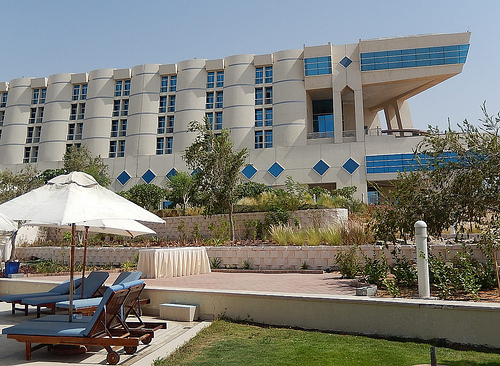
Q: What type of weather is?
A: It is clear.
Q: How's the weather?
A: It is clear.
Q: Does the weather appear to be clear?
A: Yes, it is clear.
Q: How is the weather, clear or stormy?
A: It is clear.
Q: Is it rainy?
A: No, it is clear.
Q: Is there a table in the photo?
A: Yes, there is a table.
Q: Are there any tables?
A: Yes, there is a table.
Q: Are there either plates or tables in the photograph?
A: Yes, there is a table.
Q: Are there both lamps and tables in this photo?
A: No, there is a table but no lamps.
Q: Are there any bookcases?
A: No, there are no bookcases.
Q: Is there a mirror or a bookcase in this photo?
A: No, there are no bookcases or mirrors.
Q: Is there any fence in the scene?
A: No, there are no fences.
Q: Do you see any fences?
A: No, there are no fences.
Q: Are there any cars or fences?
A: No, there are no fences or cars.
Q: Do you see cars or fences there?
A: No, there are no fences or cars.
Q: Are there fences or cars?
A: No, there are no fences or cars.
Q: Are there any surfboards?
A: No, there are no surfboards.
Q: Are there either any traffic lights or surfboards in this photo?
A: No, there are no surfboards or traffic lights.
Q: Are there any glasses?
A: No, there are no glasses.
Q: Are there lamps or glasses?
A: No, there are no glasses or lamps.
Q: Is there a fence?
A: No, there are no fences.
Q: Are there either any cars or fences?
A: No, there are no fences or cars.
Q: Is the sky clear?
A: Yes, the sky is clear.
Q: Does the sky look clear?
A: Yes, the sky is clear.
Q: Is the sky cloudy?
A: No, the sky is clear.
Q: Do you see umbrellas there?
A: Yes, there is an umbrella.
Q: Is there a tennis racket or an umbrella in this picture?
A: Yes, there is an umbrella.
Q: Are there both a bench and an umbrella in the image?
A: No, there is an umbrella but no benches.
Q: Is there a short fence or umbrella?
A: Yes, there is a short umbrella.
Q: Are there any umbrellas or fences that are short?
A: Yes, the umbrella is short.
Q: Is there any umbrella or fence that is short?
A: Yes, the umbrella is short.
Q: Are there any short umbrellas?
A: Yes, there is a short umbrella.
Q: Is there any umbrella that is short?
A: Yes, there is an umbrella that is short.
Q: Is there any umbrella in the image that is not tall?
A: Yes, there is a short umbrella.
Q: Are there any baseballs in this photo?
A: No, there are no baseballs.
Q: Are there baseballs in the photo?
A: No, there are no baseballs.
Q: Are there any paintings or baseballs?
A: No, there are no baseballs or paintings.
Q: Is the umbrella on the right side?
A: No, the umbrella is on the left of the image.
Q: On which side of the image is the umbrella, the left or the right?
A: The umbrella is on the left of the image.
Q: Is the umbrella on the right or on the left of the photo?
A: The umbrella is on the left of the image.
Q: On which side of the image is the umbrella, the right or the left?
A: The umbrella is on the left of the image.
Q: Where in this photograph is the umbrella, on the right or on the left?
A: The umbrella is on the left of the image.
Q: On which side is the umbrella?
A: The umbrella is on the left of the image.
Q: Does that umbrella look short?
A: Yes, the umbrella is short.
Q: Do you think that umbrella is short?
A: Yes, the umbrella is short.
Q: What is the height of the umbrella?
A: The umbrella is short.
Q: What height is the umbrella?
A: The umbrella is short.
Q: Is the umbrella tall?
A: No, the umbrella is short.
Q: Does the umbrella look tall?
A: No, the umbrella is short.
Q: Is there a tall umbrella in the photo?
A: No, there is an umbrella but it is short.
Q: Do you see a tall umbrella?
A: No, there is an umbrella but it is short.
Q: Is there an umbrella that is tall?
A: No, there is an umbrella but it is short.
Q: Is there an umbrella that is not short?
A: No, there is an umbrella but it is short.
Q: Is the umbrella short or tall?
A: The umbrella is short.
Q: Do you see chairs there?
A: Yes, there is a chair.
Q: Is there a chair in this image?
A: Yes, there is a chair.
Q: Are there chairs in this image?
A: Yes, there is a chair.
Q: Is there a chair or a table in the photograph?
A: Yes, there is a chair.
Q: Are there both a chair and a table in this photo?
A: Yes, there are both a chair and a table.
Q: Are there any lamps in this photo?
A: No, there are no lamps.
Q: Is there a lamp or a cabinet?
A: No, there are no lamps or cabinets.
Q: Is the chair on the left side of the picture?
A: Yes, the chair is on the left of the image.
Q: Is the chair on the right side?
A: No, the chair is on the left of the image.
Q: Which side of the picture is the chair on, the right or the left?
A: The chair is on the left of the image.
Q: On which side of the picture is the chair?
A: The chair is on the left of the image.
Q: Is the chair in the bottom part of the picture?
A: Yes, the chair is in the bottom of the image.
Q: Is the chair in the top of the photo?
A: No, the chair is in the bottom of the image.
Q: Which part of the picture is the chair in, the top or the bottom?
A: The chair is in the bottom of the image.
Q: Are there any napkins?
A: No, there are no napkins.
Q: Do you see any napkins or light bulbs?
A: No, there are no napkins or light bulbs.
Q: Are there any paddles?
A: No, there are no paddles.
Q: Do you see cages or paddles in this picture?
A: No, there are no paddles or cages.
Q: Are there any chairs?
A: Yes, there is a chair.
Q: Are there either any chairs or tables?
A: Yes, there is a chair.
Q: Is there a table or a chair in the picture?
A: Yes, there is a chair.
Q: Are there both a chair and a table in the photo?
A: Yes, there are both a chair and a table.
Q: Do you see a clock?
A: No, there are no clocks.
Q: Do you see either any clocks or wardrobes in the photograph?
A: No, there are no clocks or wardrobes.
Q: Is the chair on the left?
A: Yes, the chair is on the left of the image.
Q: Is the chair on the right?
A: No, the chair is on the left of the image.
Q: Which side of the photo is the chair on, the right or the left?
A: The chair is on the left of the image.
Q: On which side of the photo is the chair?
A: The chair is on the left of the image.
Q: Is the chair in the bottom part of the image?
A: Yes, the chair is in the bottom of the image.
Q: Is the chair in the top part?
A: No, the chair is in the bottom of the image.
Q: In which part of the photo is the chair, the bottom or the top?
A: The chair is in the bottom of the image.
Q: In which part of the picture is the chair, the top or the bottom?
A: The chair is in the bottom of the image.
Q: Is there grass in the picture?
A: Yes, there is grass.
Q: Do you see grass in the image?
A: Yes, there is grass.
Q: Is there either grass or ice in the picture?
A: Yes, there is grass.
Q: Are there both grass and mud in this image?
A: No, there is grass but no mud.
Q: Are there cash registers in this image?
A: No, there are no cash registers.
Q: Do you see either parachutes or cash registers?
A: No, there are no cash registers or parachutes.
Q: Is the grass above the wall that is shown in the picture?
A: Yes, the grass is above the wall.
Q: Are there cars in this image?
A: No, there are no cars.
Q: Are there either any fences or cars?
A: No, there are no cars or fences.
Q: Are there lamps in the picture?
A: No, there are no lamps.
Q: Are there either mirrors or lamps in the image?
A: No, there are no lamps or mirrors.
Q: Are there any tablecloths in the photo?
A: Yes, there is a tablecloth.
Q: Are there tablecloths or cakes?
A: Yes, there is a tablecloth.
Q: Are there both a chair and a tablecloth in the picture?
A: Yes, there are both a tablecloth and a chair.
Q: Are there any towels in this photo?
A: No, there are no towels.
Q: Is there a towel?
A: No, there are no towels.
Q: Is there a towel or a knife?
A: No, there are no towels or knives.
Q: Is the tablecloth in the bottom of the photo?
A: Yes, the tablecloth is in the bottom of the image.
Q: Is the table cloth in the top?
A: No, the table cloth is in the bottom of the image.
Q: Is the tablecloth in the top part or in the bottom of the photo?
A: The tablecloth is in the bottom of the image.